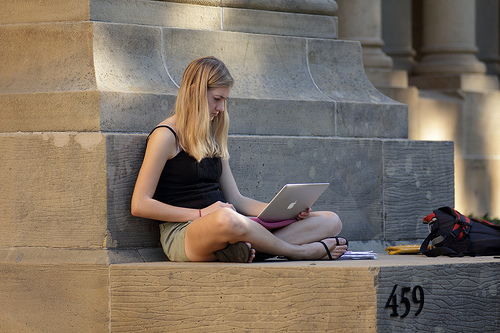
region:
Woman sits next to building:
[120, 50, 370, 270]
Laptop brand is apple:
[256, 171, 336, 231]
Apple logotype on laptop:
[283, 197, 302, 214]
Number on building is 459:
[367, 266, 450, 326]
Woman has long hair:
[126, 37, 261, 189]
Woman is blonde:
[126, 51, 251, 187]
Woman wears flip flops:
[120, 47, 370, 284]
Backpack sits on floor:
[409, 194, 499, 260]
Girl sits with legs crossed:
[125, 47, 353, 270]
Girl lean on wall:
[123, 45, 360, 278]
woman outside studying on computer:
[31, 12, 486, 299]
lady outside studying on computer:
[42, 29, 473, 293]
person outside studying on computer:
[52, 36, 461, 295]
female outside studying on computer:
[35, 32, 475, 290]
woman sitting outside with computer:
[40, 24, 464, 282]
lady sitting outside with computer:
[26, 34, 463, 294]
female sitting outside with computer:
[55, 26, 434, 287]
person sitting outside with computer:
[59, 8, 446, 282]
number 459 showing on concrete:
[362, 271, 436, 322]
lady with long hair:
[155, 48, 242, 153]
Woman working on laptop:
[130, 36, 364, 294]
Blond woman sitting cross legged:
[124, 52, 362, 266]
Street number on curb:
[367, 282, 437, 326]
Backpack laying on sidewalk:
[402, 193, 497, 274]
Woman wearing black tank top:
[131, 53, 343, 283]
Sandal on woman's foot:
[301, 235, 352, 265]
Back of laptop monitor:
[257, 169, 352, 257]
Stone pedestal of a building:
[7, 25, 458, 246]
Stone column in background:
[402, 3, 490, 81]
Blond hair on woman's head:
[148, 52, 250, 160]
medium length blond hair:
[175, 55, 234, 160]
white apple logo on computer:
[285, 196, 298, 209]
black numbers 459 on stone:
[383, 281, 425, 321]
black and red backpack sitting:
[418, 202, 498, 257]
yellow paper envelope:
[389, 240, 429, 260]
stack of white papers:
[342, 246, 377, 259]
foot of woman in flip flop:
[295, 236, 351, 263]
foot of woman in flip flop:
[221, 238, 261, 266]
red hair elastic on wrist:
[195, 203, 208, 220]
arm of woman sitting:
[130, 126, 234, 230]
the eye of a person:
[213, 95, 223, 103]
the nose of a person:
[216, 99, 225, 113]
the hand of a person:
[123, 126, 229, 223]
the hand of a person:
[220, 150, 317, 219]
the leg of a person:
[192, 212, 359, 267]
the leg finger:
[334, 233, 347, 245]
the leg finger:
[333, 243, 349, 249]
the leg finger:
[334, 246, 347, 255]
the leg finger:
[328, 253, 341, 262]